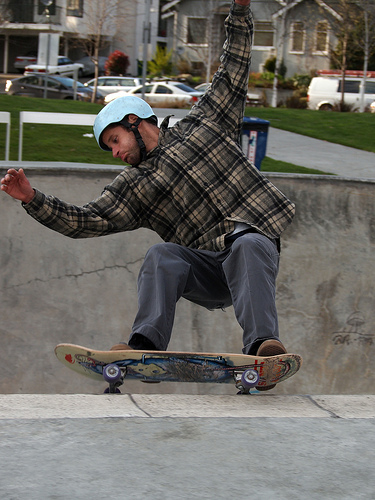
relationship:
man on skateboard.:
[2, 0, 295, 357] [42, 291, 328, 416]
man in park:
[19, 15, 315, 360] [21, 1, 374, 347]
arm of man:
[194, 0, 255, 136] [2, 0, 295, 357]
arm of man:
[0, 167, 136, 240] [2, 0, 295, 357]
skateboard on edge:
[54, 334, 301, 395] [1, 388, 373, 404]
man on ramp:
[2, 0, 295, 357] [2, 31, 373, 441]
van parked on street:
[307, 75, 375, 116] [292, 37, 329, 197]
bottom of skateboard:
[176, 362, 242, 405] [58, 340, 301, 426]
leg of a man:
[215, 227, 295, 356] [2, 1, 323, 401]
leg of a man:
[221, 227, 282, 340] [153, 157, 235, 331]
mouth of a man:
[119, 147, 128, 164] [0, 7, 323, 353]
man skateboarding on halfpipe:
[2, 0, 295, 357] [183, 378, 339, 472]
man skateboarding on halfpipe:
[2, 0, 295, 357] [191, 387, 353, 434]